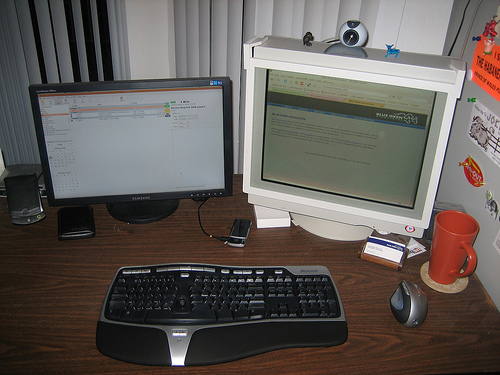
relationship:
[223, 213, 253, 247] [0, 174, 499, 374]
cellphone on desk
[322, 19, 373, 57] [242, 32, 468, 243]
web cam on top of monitor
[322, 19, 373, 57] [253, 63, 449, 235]
web cam on screen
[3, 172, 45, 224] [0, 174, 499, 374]
gray speaker on desk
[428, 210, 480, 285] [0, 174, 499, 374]
coffee mug on desk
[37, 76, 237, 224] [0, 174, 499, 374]
black monitor on desk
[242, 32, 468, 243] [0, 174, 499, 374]
monitor on desk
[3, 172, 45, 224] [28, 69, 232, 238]
gray speaker sits next to left of monitor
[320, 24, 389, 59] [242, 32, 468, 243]
web cam placed on top of monitor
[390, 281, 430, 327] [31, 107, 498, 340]
computer mouse on desk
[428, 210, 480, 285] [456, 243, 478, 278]
coffee mug has a cup handle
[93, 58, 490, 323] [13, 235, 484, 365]
black monitor on a desk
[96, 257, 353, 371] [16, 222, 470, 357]
keyboard on a desk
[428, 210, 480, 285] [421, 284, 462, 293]
coffee mug on a coaster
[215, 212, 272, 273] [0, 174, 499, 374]
cellphone on a desk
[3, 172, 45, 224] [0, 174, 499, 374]
gray speaker on a desk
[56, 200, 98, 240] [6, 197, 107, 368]
wallet on a desk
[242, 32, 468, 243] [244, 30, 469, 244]
monitor to a computer monitor